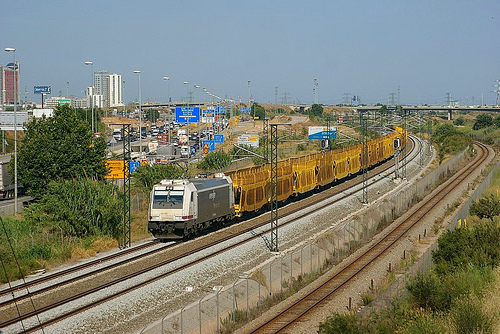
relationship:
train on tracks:
[136, 139, 366, 254] [126, 234, 387, 325]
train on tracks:
[146, 126, 407, 243] [290, 188, 339, 222]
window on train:
[151, 194, 183, 209] [146, 111, 436, 226]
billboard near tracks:
[299, 112, 348, 142] [134, 80, 484, 275]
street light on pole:
[3, 45, 18, 55] [11, 52, 20, 215]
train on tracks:
[146, 126, 407, 243] [28, 101, 481, 331]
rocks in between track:
[163, 251, 209, 278] [7, 239, 234, 332]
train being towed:
[146, 126, 407, 243] [138, 119, 411, 234]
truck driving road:
[157, 141, 180, 160] [102, 134, 172, 158]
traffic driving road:
[143, 137, 198, 162] [123, 108, 212, 168]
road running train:
[97, 115, 220, 182] [146, 126, 407, 243]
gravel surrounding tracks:
[248, 219, 343, 267] [55, 213, 460, 318]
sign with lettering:
[179, 104, 201, 119] [128, 164, 143, 179]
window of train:
[151, 194, 184, 206] [152, 186, 189, 209]